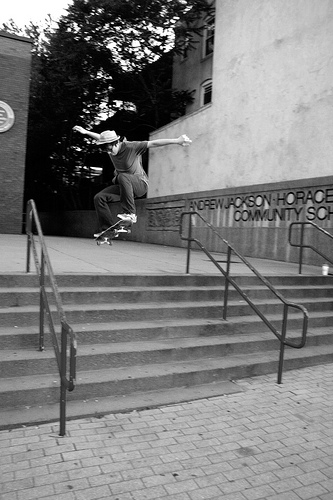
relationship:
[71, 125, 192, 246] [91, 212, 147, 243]
boy on skateboard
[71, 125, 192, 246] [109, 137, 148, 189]
boy wearing shirt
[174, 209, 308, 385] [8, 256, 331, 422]
rail on stair case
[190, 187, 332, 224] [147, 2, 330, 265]
writing on wall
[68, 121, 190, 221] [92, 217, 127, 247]
boy on skateboard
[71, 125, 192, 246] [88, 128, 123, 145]
boy in hat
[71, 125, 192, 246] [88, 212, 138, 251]
boy skating on skateboard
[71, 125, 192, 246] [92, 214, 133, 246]
boy skating on skateboard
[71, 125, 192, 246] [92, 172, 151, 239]
boy in pants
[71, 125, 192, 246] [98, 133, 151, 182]
boy in t-shirt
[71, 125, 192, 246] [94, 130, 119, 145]
boy wearing hat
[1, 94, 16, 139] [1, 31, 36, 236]
sign on building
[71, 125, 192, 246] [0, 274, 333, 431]
boy jumping stair case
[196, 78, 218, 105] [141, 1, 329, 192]
window on side building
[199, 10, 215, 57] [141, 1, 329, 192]
window on side building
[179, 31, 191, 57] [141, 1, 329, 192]
window on side building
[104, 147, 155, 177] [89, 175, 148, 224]
shirt and pants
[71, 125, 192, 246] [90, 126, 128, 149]
boy wearing hat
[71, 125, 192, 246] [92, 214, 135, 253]
boy on skateboard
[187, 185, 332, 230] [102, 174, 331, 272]
sign on wall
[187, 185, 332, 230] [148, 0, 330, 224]
sign on building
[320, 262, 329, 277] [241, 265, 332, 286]
cup on step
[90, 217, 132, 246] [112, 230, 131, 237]
skateboard with four wheels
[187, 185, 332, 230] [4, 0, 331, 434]
sign on community school